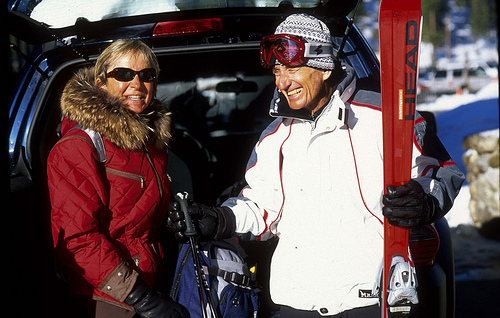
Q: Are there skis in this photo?
A: Yes, there are skis.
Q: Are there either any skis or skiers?
A: Yes, there are skis.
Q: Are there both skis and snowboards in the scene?
A: No, there are skis but no snowboards.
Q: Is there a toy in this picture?
A: No, there are no toys.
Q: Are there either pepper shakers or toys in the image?
A: No, there are no toys or pepper shakers.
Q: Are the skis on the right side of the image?
A: Yes, the skis are on the right of the image.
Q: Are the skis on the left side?
A: No, the skis are on the right of the image.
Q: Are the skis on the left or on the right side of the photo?
A: The skis are on the right of the image.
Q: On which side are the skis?
A: The skis are on the right of the image.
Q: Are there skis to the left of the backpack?
A: No, the skis are to the right of the backpack.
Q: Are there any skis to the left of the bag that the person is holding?
A: No, the skis are to the right of the backpack.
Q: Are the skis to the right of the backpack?
A: Yes, the skis are to the right of the backpack.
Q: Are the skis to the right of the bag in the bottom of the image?
A: Yes, the skis are to the right of the backpack.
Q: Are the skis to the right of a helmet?
A: No, the skis are to the right of the backpack.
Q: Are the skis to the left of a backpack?
A: No, the skis are to the right of a backpack.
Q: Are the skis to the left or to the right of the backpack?
A: The skis are to the right of the backpack.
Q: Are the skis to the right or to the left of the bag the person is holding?
A: The skis are to the right of the backpack.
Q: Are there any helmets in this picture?
A: No, there are no helmets.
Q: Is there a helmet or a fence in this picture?
A: No, there are no helmets or fences.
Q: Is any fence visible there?
A: No, there are no fences.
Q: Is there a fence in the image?
A: No, there are no fences.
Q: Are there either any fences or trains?
A: No, there are no fences or trains.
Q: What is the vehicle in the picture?
A: The vehicle is a car.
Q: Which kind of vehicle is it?
A: The vehicle is a car.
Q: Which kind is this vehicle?
A: This is a car.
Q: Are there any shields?
A: No, there are no shields.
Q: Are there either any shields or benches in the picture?
A: No, there are no shields or benches.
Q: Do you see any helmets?
A: No, there are no helmets.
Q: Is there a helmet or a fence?
A: No, there are no helmets or fences.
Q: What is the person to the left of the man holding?
A: The person is holding the backpack.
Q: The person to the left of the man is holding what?
A: The person is holding the backpack.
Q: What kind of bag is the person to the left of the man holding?
A: The person is holding the backpack.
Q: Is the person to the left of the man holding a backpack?
A: Yes, the person is holding a backpack.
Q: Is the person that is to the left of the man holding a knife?
A: No, the person is holding a backpack.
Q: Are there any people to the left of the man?
A: Yes, there is a person to the left of the man.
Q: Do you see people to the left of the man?
A: Yes, there is a person to the left of the man.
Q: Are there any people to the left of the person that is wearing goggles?
A: Yes, there is a person to the left of the man.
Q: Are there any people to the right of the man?
A: No, the person is to the left of the man.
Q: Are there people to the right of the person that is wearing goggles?
A: No, the person is to the left of the man.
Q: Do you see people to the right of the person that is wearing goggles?
A: No, the person is to the left of the man.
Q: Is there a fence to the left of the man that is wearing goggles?
A: No, there is a person to the left of the man.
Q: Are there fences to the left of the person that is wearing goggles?
A: No, there is a person to the left of the man.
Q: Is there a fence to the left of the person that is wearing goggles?
A: No, there is a person to the left of the man.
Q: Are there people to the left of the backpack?
A: Yes, there is a person to the left of the backpack.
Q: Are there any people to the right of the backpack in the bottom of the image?
A: No, the person is to the left of the backpack.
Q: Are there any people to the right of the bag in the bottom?
A: No, the person is to the left of the backpack.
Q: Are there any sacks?
A: No, there are no sacks.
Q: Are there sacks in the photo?
A: No, there are no sacks.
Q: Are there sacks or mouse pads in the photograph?
A: No, there are no sacks or mouse pads.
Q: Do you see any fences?
A: No, there are no fences.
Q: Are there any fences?
A: No, there are no fences.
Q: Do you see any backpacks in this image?
A: Yes, there is a backpack.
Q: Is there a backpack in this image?
A: Yes, there is a backpack.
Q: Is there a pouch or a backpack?
A: Yes, there is a backpack.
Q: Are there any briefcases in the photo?
A: No, there are no briefcases.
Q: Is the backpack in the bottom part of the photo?
A: Yes, the backpack is in the bottom of the image.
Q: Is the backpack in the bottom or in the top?
A: The backpack is in the bottom of the image.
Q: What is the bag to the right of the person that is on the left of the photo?
A: The bag is a backpack.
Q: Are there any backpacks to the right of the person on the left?
A: Yes, there is a backpack to the right of the person.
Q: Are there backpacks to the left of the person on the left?
A: No, the backpack is to the right of the person.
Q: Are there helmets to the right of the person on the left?
A: No, there is a backpack to the right of the person.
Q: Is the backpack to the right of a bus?
A: No, the backpack is to the right of the person.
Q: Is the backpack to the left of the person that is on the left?
A: No, the backpack is to the right of the person.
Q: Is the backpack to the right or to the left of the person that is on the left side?
A: The backpack is to the right of the person.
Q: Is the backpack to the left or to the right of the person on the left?
A: The backpack is to the right of the person.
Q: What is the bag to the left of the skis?
A: The bag is a backpack.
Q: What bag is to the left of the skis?
A: The bag is a backpack.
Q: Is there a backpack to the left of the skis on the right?
A: Yes, there is a backpack to the left of the skis.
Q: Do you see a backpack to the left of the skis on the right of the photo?
A: Yes, there is a backpack to the left of the skis.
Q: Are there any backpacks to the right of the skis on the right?
A: No, the backpack is to the left of the skis.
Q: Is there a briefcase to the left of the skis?
A: No, there is a backpack to the left of the skis.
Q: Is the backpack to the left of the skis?
A: Yes, the backpack is to the left of the skis.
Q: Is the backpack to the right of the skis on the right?
A: No, the backpack is to the left of the skis.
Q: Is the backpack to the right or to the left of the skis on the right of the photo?
A: The backpack is to the left of the skis.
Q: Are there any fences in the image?
A: No, there are no fences.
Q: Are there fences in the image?
A: No, there are no fences.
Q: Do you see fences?
A: No, there are no fences.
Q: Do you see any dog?
A: No, there are no dogs.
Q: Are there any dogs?
A: No, there are no dogs.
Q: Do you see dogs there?
A: No, there are no dogs.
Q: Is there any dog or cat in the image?
A: No, there are no dogs or cats.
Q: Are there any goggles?
A: Yes, there are goggles.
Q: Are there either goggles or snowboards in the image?
A: Yes, there are goggles.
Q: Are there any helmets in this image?
A: No, there are no helmets.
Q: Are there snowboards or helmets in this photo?
A: No, there are no helmets or snowboards.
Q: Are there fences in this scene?
A: No, there are no fences.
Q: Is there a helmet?
A: No, there are no helmets.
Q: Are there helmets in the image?
A: No, there are no helmets.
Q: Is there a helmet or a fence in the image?
A: No, there are no helmets or fences.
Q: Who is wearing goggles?
A: The man is wearing goggles.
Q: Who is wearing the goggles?
A: The man is wearing goggles.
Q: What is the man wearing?
A: The man is wearing goggles.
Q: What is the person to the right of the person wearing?
A: The man is wearing goggles.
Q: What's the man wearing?
A: The man is wearing goggles.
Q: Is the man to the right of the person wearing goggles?
A: Yes, the man is wearing goggles.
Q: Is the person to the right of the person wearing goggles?
A: Yes, the man is wearing goggles.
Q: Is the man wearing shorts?
A: No, the man is wearing goggles.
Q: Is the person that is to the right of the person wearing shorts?
A: No, the man is wearing goggles.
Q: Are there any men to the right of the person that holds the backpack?
A: Yes, there is a man to the right of the person.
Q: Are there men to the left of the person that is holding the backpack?
A: No, the man is to the right of the person.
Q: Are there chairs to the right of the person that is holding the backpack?
A: No, there is a man to the right of the person.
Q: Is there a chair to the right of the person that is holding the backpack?
A: No, there is a man to the right of the person.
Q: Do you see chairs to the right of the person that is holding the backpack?
A: No, there is a man to the right of the person.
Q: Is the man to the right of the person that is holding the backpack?
A: Yes, the man is to the right of the person.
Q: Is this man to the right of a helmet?
A: No, the man is to the right of the person.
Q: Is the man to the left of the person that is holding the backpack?
A: No, the man is to the right of the person.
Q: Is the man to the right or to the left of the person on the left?
A: The man is to the right of the person.